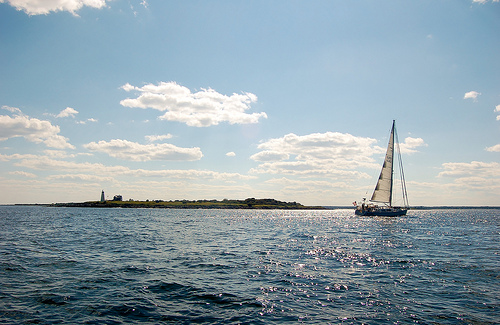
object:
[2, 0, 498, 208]
sky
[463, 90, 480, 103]
clouds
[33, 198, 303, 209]
land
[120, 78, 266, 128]
cloud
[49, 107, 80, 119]
cloud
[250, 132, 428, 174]
cloud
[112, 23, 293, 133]
blue sky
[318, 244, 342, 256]
sunlight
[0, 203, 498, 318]
ocean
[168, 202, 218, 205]
grass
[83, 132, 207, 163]
cloud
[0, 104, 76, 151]
cloud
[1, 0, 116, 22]
cloud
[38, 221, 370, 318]
blue water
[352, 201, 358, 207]
flag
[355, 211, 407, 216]
blue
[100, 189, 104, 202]
lighthouse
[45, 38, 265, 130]
clouds sky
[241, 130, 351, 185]
clouds sky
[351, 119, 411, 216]
boat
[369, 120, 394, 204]
sail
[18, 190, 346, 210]
island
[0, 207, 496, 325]
water